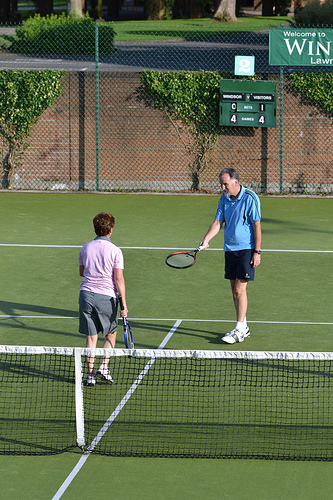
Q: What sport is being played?
A: Tennis.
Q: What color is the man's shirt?
A: Blue.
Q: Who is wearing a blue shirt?
A: Instructor.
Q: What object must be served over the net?
A: Tennis ball.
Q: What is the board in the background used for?
A: To keep score.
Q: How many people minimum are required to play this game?
A: 2.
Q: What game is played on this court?
A: Tennis.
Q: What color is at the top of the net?
A: White.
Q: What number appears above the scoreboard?
A: 2.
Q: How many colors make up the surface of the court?
A: 2.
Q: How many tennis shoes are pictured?
A: 4.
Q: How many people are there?
A: Two.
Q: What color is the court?
A: Green.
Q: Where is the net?
A: Behind the woman.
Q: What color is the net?
A: Black and white.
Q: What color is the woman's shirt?
A: Lavender.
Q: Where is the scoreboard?
A: On the fence.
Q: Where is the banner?
A: Above the scoreboard.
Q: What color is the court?
A: Green.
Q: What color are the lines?
A: White.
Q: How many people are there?
A: Two.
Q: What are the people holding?
A: Tennis rackets.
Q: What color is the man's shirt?
A: Blue.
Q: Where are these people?
A: Tennis court.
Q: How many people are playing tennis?
A: Two.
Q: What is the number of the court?
A: 2.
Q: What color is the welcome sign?
A: Green and white.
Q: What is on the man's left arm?
A: A watch.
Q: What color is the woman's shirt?
A: Pink.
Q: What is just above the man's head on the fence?
A: The scoreboard.